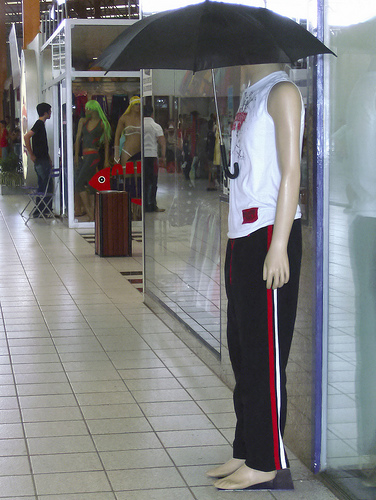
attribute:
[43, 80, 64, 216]
window — store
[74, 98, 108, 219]
mannequin — wearing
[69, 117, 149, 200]
clothing — skimpy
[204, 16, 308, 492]
mannequin — headless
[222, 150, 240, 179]
handle — black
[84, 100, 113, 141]
wig — green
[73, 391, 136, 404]
floor tile — Single piece, floor 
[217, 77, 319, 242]
shirt — white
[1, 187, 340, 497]
floor — tile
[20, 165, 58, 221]
chair — purple, folding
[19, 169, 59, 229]
chair — blue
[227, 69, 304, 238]
shirt — short sleeved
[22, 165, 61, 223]
chair — plastic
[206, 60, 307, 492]
mannequin — head  , missing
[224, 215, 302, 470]
pants — striped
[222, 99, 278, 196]
shirt — white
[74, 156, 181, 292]
trash — wooden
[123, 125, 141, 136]
bra — see through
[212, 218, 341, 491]
pants — pair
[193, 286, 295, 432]
pants — black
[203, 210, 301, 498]
pants — black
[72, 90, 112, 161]
hair — green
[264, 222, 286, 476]
stripes — red , white 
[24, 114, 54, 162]
shirt — black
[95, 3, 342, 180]
umbrella — black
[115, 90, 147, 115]
hair — yellow